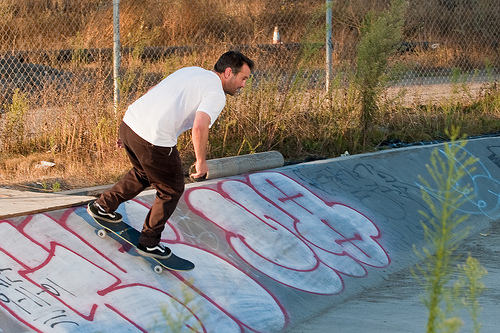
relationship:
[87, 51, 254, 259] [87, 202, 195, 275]
man on board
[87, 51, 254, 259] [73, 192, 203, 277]
man on skateboard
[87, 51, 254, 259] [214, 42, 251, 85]
man with hair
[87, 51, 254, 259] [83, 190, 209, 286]
man riding skateboard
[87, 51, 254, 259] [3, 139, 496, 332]
man riding down slope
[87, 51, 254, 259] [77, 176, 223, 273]
man on board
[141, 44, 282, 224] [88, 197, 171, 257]
man wearing shoes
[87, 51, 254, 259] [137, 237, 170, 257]
man wearing shoe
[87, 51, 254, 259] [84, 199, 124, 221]
man wearing shoe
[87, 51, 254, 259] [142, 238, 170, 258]
man wearing shoe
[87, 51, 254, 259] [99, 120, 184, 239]
man wearing pants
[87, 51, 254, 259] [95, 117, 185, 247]
man wearing pants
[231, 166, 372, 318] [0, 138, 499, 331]
graffiti on pavement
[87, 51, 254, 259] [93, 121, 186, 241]
man wearing pants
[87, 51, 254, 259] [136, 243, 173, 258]
man wearing shoe